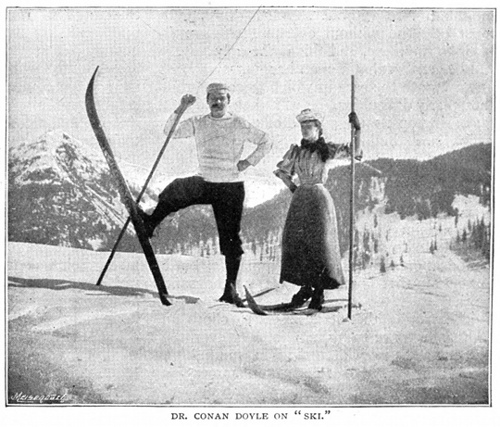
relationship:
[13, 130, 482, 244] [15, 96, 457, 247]
mountains in background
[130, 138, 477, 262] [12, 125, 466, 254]
trees along horizon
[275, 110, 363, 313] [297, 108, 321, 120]
lady wearing hat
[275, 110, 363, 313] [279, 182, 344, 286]
lady wearing skirt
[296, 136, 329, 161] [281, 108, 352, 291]
scarf around lady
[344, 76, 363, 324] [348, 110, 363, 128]
ski pole in hand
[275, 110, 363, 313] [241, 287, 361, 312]
lady wearing skis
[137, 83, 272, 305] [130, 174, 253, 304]
man wearing pants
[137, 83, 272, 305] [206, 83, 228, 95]
man wearing hat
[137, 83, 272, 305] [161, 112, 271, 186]
man wearing shirt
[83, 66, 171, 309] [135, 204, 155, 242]
ski on foot